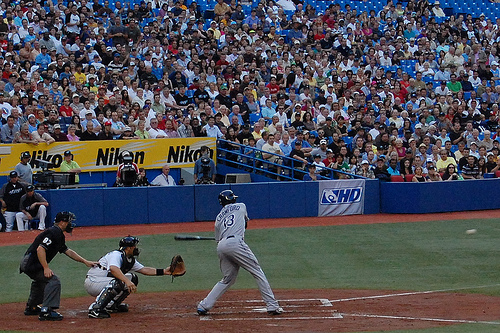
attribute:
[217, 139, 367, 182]
railing — blue , metal 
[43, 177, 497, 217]
padding — blue 